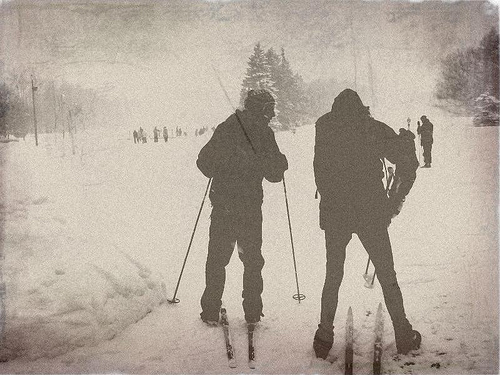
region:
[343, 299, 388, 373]
two skis covered in snow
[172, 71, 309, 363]
person holding two ski poles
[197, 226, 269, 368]
two legs over two skis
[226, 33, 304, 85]
top of several evergreen trees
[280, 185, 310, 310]
one metal ski pole in the snow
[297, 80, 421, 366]
silhouette of man in snow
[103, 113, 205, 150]
several people standing in the snow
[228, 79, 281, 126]
side of man wearing hat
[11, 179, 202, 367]
ski pole next to small snow bank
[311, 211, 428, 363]
two legs standing apart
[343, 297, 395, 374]
A pair of skis beneath the man on the right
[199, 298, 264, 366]
A pair of skis on the left man's feet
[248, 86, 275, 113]
The man on the left is wearing a hat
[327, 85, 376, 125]
The man on the right is wearing a black hood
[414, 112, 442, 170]
A man standing in the snow past the skiers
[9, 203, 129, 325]
A large mound of snow by the men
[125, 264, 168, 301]
Ski pole marks in the snow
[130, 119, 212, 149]
A group of people walking in the distance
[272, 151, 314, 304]
A ski pole in the man's hand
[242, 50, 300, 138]
Snow covered trees in the distance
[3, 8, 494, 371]
two people skiing on the snow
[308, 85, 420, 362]
male; right has back facing camera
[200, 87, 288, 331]
male; left ,back faces camera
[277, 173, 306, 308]
male; left holding ski in hand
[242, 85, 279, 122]
male; left wearing winter hat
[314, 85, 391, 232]
male; right wearing jacket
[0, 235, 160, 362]
snow makes a path for the skiiers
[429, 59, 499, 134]
snow covered tree on snowy path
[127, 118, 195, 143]
groups of people in distance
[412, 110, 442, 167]
a figure of person facing left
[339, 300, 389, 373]
Skis on the snow.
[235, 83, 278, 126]
Skier wearing a hat.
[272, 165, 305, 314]
Black ski pole in person's hand.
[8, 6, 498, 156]
Blowing snow in the background.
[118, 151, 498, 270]
White snow on the ground.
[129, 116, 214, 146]
People standing in the background.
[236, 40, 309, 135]
Pine trees in the background.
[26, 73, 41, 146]
Light pole in the background.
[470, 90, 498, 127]
Snow on bush in the background.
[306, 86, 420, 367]
Person wearing a winter jacket.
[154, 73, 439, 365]
two man on the snow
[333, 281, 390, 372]
two skis below a man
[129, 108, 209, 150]
a group of people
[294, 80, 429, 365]
man wears black cloths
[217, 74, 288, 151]
man wears a cap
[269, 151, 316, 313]
a snow pole on right side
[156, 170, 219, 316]
a snow pole on left side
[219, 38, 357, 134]
three pines on a field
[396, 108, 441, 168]
people holding snow skis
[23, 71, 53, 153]
a pole on left side